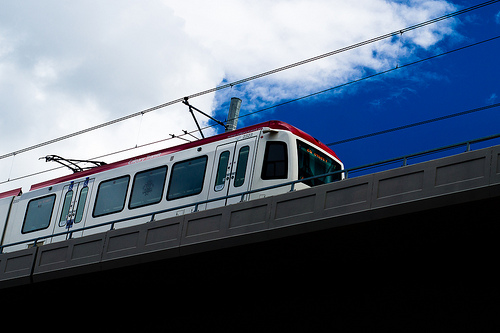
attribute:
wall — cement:
[0, 139, 499, 303]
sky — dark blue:
[417, 81, 479, 108]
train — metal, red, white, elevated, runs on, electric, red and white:
[0, 119, 349, 256]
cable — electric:
[7, 77, 258, 180]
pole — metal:
[219, 85, 246, 139]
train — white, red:
[31, 109, 356, 222]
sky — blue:
[209, 28, 499, 180]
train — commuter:
[46, 152, 310, 199]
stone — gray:
[2, 140, 495, 297]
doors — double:
[215, 141, 286, 215]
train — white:
[26, 117, 361, 228]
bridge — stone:
[1, 144, 498, 281]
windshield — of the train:
[294, 135, 344, 185]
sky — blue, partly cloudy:
[2, 1, 499, 201]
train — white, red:
[2, 104, 358, 261]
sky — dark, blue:
[1, 1, 498, 178]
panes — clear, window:
[71, 139, 208, 233]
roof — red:
[0, 116, 345, 205]